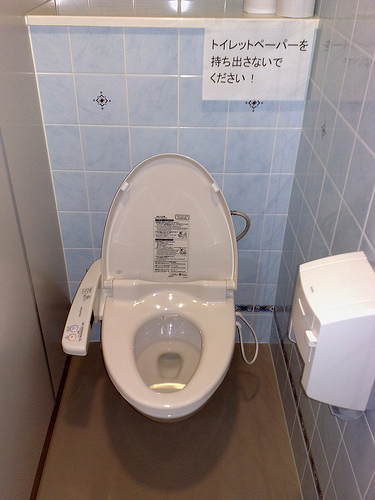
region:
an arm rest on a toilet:
[61, 251, 104, 358]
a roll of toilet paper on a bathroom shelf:
[276, 0, 319, 17]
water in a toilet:
[137, 339, 201, 394]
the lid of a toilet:
[99, 150, 238, 280]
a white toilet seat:
[104, 278, 240, 418]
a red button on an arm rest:
[67, 332, 76, 341]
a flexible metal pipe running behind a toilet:
[227, 207, 254, 246]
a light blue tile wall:
[27, 25, 320, 341]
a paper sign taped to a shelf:
[198, 17, 317, 96]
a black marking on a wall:
[92, 86, 112, 114]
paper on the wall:
[235, 60, 306, 99]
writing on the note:
[203, 30, 299, 93]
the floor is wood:
[236, 466, 270, 484]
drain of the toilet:
[152, 352, 183, 377]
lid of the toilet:
[122, 197, 212, 270]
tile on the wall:
[126, 39, 171, 129]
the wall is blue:
[247, 148, 263, 164]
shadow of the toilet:
[117, 436, 216, 490]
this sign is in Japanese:
[186, 2, 338, 126]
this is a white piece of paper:
[185, 8, 336, 117]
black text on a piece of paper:
[203, 27, 317, 101]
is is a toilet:
[57, 135, 284, 449]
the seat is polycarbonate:
[0, 150, 261, 426]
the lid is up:
[87, 139, 290, 434]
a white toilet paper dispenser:
[278, 228, 373, 438]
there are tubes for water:
[219, 196, 271, 379]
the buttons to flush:
[52, 264, 99, 380]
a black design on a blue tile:
[89, 84, 120, 116]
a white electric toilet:
[64, 153, 255, 418]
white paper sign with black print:
[204, 18, 310, 99]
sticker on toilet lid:
[153, 211, 189, 277]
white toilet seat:
[96, 279, 235, 414]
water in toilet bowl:
[137, 339, 195, 394]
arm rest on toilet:
[61, 256, 103, 353]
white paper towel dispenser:
[285, 251, 371, 410]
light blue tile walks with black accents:
[29, 2, 370, 494]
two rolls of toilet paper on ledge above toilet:
[244, 0, 311, 18]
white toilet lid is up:
[100, 152, 237, 281]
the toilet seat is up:
[70, 144, 252, 406]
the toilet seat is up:
[72, 139, 265, 448]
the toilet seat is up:
[78, 134, 251, 434]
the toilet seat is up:
[73, 147, 245, 463]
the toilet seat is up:
[73, 171, 251, 445]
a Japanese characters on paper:
[182, 21, 305, 123]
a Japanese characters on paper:
[181, 23, 334, 119]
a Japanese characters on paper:
[182, 25, 312, 131]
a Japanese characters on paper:
[177, 25, 335, 130]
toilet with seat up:
[60, 154, 254, 421]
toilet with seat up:
[50, 142, 272, 420]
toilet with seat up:
[54, 143, 272, 419]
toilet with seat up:
[54, 143, 265, 419]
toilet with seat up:
[42, 145, 264, 419]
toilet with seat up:
[59, 150, 270, 420]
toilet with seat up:
[53, 148, 253, 418]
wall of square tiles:
[28, 25, 313, 341]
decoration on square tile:
[75, 72, 129, 125]